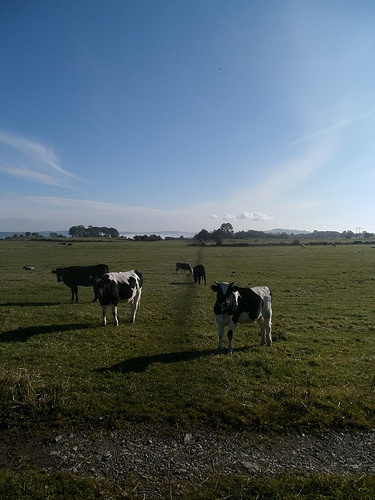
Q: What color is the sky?
A: Blue.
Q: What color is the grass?
A: Green.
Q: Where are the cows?
A: In a field.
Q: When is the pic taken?
A: Daytime.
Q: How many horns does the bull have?
A: Two.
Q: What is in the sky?
A: Clouds.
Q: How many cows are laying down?
A: One.